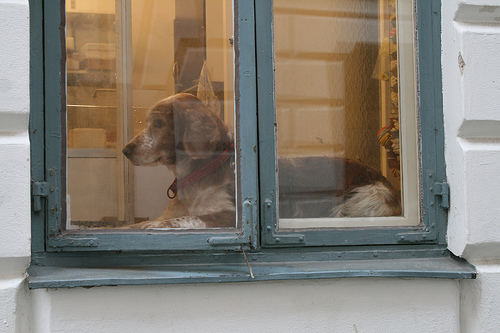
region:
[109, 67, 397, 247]
One dog is inside the house.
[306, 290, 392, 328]
Walls are white color.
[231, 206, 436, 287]
Window frame is grey color.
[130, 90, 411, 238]
Dog is sitting in the window.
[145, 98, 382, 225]
Dog is brown color.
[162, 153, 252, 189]
Dog collar is red color.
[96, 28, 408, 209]
Reflection is seen in window glass.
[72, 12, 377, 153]
Lights are on inside the house.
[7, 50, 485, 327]
Day time picture.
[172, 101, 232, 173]
Dog has two small ears.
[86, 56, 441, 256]
dog is sitting by the window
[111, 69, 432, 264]
the dog is brown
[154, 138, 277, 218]
the collar is red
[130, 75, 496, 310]
tone dog is sitting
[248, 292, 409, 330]
the wall is white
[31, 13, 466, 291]
the window pane is blue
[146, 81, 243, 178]
the dog has ears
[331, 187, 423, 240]
the tale is white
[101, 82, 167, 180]
the nose is brown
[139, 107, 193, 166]
dog's eyes are open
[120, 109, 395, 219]
A dog facing to the left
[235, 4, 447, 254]
A blue-green colored window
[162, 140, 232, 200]
A red collar around the dog's neck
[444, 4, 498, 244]
A white painted wall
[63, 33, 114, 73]
A bunch of boxes at the back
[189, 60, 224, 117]
A piece of clothing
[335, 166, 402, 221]
The furry tail of a dog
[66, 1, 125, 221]
A cabinet filled with boxes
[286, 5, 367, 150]
A white wall inside the house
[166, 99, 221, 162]
The dog's long right ear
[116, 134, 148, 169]
a dog's black nose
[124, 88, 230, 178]
A dog's head and ears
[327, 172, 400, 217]
a dog's tail.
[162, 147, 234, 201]
a dog's red collar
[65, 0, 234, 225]
a window pane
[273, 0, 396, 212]
another window pane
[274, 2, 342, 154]
a reflection of a wall outside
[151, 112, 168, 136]
a dog's eye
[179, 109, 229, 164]
a dog's brown ear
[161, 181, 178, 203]
a round leash hook on the dog's collar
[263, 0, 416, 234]
a window on a house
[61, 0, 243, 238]
a window on a house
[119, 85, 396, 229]
a dog inside a house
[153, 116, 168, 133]
a brown dog's eye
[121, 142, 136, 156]
a brown dog's nose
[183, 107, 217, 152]
a brown dog's ear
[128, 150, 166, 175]
a brown dog's mouth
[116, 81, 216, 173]
a brown dog's head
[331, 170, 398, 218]
a brown dog's tail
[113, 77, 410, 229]
a brown dog